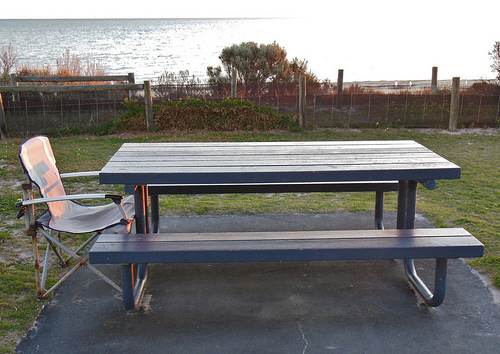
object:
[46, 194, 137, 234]
seat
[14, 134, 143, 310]
chair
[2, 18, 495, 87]
ocean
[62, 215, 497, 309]
ground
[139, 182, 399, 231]
bench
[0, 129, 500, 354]
field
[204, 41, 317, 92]
bush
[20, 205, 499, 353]
grey ground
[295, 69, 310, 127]
fence post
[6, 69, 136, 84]
crossmember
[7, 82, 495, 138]
fence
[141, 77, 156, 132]
fence post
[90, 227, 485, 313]
bench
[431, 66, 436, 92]
post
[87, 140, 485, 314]
picnic table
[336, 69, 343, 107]
post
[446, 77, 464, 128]
fence post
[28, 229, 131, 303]
legs